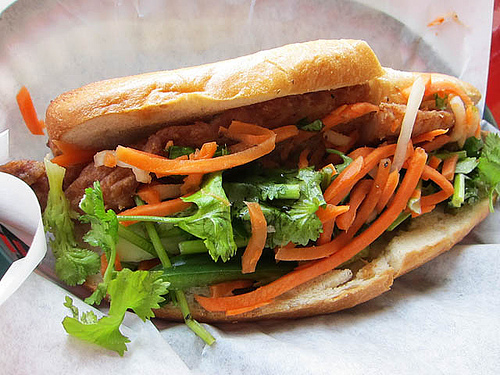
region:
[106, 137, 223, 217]
a sandwich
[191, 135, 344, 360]
a sandwich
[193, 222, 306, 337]
a sandwich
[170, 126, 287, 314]
a sandwich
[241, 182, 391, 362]
a sandwich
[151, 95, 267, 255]
a sandwich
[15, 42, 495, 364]
sandwich laying on wax paper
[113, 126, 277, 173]
long, orange, shred of carrot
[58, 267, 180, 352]
light green leaf of lettuce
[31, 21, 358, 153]
thick bread bun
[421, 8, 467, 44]
bit of sauce that got on the wax paper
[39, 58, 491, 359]
sandwich overflowing with its contents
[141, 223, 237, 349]
thin green stick of food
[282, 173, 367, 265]
orange carrot and green lettuce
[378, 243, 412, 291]
small tear in the bread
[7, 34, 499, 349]
sandwich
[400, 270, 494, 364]
the paper is white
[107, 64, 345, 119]
the bread is brown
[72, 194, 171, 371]
the parsley is green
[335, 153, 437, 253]
the carrots are shredded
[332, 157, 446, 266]
the carrots are orange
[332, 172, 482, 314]
the carrots on sandwich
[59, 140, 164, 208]
meat on the sandwich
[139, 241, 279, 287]
the peppers are green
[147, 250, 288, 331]
peppers on the sandwich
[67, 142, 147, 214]
the meat is brown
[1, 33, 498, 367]
an almost vegetarian sandwich - but probably w/ chicken on it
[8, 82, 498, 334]
thinly hand chopped carrots, maybe even on a mandoline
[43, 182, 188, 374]
parsley, i think, not cilantro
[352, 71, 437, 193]
onion shred or jicama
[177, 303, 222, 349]
a bent stem of vegetable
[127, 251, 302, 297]
slice of green bell pepper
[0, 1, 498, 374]
white wax deli paper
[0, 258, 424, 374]
some wrinkles in white wax deli paper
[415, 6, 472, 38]
a sauce stain on white wax deli paper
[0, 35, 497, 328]
a nice sourdough roll, vegetables in the middle, up top some sort of animal i dont recognize, fried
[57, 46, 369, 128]
sandwich on toasted bread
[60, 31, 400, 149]
toasted bread is light brown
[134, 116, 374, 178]
sliced carrots on sandwich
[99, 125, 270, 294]
lettuce on sandwich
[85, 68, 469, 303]
sandwich on parchment paper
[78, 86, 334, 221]
meat inside light bread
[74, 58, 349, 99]
white bread is toasted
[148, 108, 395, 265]
vegetables inside bread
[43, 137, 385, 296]
meat and vegetables in sandwich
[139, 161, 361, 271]
green lettuce on sandwich